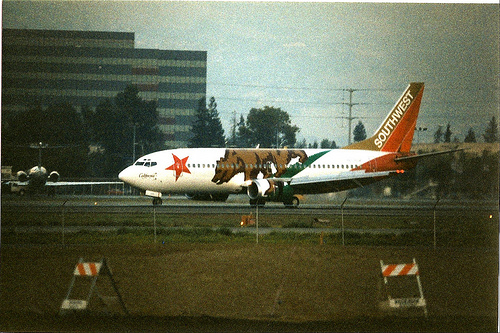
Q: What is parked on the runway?
A: A plane.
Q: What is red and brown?
A: A plane.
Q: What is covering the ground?
A: Grass.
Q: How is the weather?
A: Overcast.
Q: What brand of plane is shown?
A: Southwest.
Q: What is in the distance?
A: A building.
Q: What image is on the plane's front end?
A: A star.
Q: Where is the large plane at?
A: The runway.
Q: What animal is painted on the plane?
A: A bear.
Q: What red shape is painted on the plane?
A: A star.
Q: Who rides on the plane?
A: Passangers.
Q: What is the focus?
A: Airplane taking off.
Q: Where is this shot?
A: Runway.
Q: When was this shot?
A: Daytime.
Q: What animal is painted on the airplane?
A: Bear.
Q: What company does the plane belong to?
A: Southwest.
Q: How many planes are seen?
A: 1.